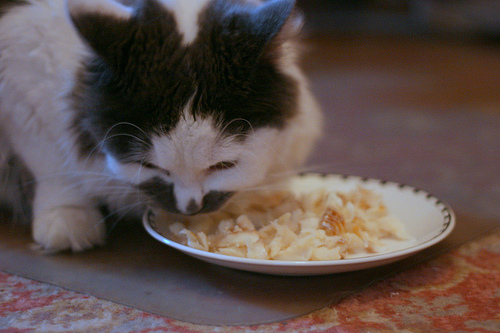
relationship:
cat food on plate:
[167, 184, 412, 259] [142, 171, 455, 277]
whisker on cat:
[82, 121, 158, 164] [0, 0, 325, 252]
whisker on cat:
[211, 115, 258, 146] [0, 0, 325, 252]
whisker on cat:
[97, 193, 163, 239] [0, 0, 325, 252]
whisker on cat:
[10, 173, 120, 194] [0, 0, 325, 252]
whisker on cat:
[213, 153, 262, 191] [0, 0, 325, 252]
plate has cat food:
[142, 171, 455, 277] [167, 184, 412, 259]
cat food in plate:
[167, 184, 412, 259] [142, 171, 455, 277]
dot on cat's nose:
[186, 196, 200, 216] [169, 182, 205, 215]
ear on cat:
[210, 0, 298, 83] [0, 0, 325, 252]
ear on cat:
[65, 0, 154, 73] [0, 0, 325, 252]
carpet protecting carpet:
[0, 0, 499, 333] [0, 0, 499, 333]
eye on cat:
[140, 162, 159, 173] [0, 0, 325, 252]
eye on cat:
[209, 157, 238, 171] [0, 0, 325, 252]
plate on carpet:
[142, 171, 455, 277] [0, 0, 499, 333]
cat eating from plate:
[0, 0, 325, 252] [142, 171, 455, 277]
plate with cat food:
[142, 171, 455, 277] [167, 184, 412, 259]